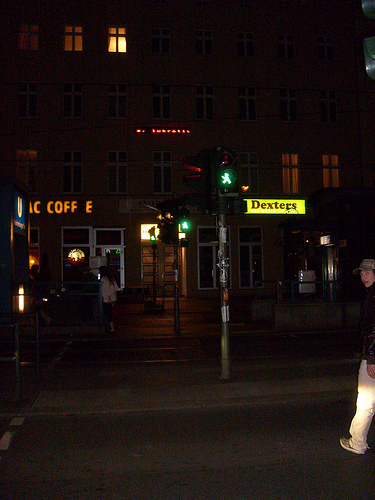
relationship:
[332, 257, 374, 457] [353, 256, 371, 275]
man wearing hat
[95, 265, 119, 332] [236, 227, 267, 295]
woman across from window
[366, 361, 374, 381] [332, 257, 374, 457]
hand of man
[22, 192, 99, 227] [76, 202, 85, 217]
sign with letter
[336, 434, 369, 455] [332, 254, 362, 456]
shoe on man